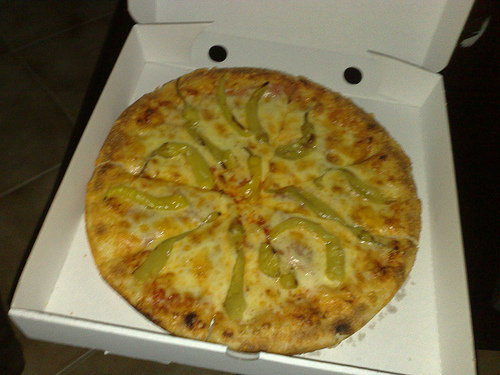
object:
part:
[241, 239, 327, 348]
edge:
[313, 312, 361, 347]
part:
[98, 163, 217, 254]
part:
[102, 171, 212, 242]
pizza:
[115, 66, 410, 334]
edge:
[325, 313, 355, 336]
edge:
[336, 311, 373, 341]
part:
[92, 162, 222, 252]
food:
[67, 54, 408, 364]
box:
[395, 310, 448, 359]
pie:
[124, 48, 427, 366]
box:
[382, 330, 440, 360]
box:
[129, 57, 169, 87]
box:
[403, 310, 447, 355]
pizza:
[124, 57, 436, 354]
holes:
[207, 36, 363, 93]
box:
[395, 308, 441, 354]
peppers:
[204, 240, 264, 320]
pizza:
[77, 54, 424, 372]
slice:
[243, 230, 328, 353]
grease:
[378, 303, 403, 329]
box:
[377, 301, 439, 365]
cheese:
[296, 152, 320, 176]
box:
[414, 305, 468, 363]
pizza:
[57, 45, 416, 347]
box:
[419, 305, 443, 355]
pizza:
[89, 48, 409, 348]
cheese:
[195, 251, 221, 281]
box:
[386, 302, 438, 360]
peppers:
[224, 245, 245, 325]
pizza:
[79, 60, 440, 330]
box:
[368, 316, 435, 358]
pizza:
[128, 66, 406, 352]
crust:
[300, 327, 335, 347]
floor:
[2, 1, 497, 371]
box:
[9, 0, 485, 373]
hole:
[196, 26, 238, 68]